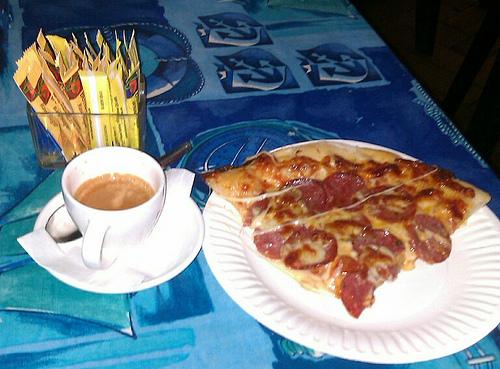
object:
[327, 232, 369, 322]
pepperoni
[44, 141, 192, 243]
spoon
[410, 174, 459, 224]
cheese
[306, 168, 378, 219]
pepperoni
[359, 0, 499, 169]
floor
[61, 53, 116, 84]
objects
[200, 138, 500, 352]
dish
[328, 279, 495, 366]
plate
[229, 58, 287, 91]
anchor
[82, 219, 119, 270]
handle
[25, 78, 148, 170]
container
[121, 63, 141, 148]
packets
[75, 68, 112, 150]
packets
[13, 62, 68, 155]
packets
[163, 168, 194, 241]
napkin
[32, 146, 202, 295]
coffee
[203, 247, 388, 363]
paper plate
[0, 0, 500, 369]
table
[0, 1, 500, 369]
blue tablecloth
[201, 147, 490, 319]
pepperoni pizza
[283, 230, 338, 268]
pepperoni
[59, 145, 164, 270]
cup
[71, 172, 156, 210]
tea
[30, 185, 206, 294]
saucer